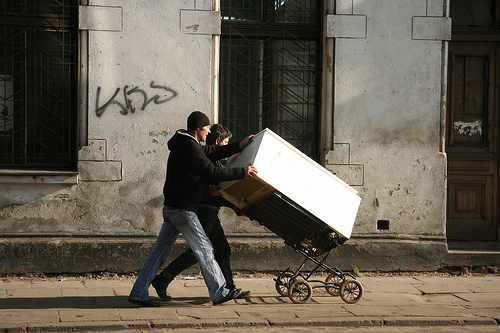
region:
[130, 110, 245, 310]
two men pushing appliance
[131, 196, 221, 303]
blue jeans on man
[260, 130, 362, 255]
white appliance on cart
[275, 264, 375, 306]
four wheels on cart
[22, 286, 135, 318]
shadow of man on sidewalk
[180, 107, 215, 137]
hat on man's head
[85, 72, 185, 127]
black spray paint on wall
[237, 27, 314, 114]
bars on front of window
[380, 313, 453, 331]
curb on edge of sidewalk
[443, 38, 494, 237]
wood door on building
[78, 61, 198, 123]
black graffiti on wall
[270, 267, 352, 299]
cart has black wheels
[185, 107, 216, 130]
man wears black hat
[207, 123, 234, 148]
man has dark hair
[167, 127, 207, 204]
man has black coat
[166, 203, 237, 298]
man has blue jeans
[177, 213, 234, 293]
man has dark pants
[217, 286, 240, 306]
man wears black shoes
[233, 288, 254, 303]
man wears brown shoes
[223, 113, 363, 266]
men are pushing appliance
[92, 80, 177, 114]
graffiti on the wall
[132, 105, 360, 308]
two men pushing a refrigerator down the street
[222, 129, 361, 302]
white refrigerator on a cart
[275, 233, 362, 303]
old four-wheeled cart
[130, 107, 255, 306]
man in blue jeans and a dark hat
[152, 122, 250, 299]
Man with dark pants and no hat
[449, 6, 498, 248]
brown door to the building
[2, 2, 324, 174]
two windows with bars on them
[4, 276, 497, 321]
brick sidewalk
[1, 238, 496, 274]
gray concrete foundation of the building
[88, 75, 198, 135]
graffiti on the wall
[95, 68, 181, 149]
the graffiti is black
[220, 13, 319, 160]
bars on the window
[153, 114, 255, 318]
the two men walking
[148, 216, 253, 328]
the men are wearing jeans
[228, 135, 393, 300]
fridge is on the cart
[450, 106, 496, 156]
paper on the door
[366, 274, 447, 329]
the sidewalk is brown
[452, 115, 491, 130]
the numbers are black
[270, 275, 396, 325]
the wheels are brown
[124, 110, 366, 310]
two men pushing fridge on cart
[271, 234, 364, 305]
a cart with four wheels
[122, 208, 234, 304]
pair of light blue jeans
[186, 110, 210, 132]
black beanie on head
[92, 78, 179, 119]
black graffiti on wall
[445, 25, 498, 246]
half of a brown door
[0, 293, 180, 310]
shadow from men on sidewalk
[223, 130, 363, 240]
a small white refrigerator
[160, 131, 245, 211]
a long sleeved black sweatshirt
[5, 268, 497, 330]
a light stoned walkway